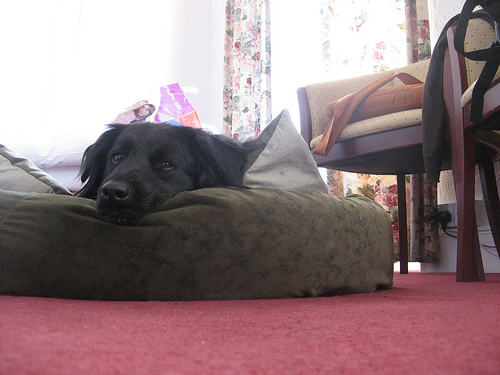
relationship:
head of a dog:
[95, 122, 199, 221] [75, 115, 258, 234]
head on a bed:
[95, 122, 199, 221] [5, 146, 396, 309]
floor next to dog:
[1, 270, 500, 372] [75, 115, 258, 234]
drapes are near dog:
[223, 1, 437, 267] [75, 115, 258, 234]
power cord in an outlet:
[435, 207, 497, 251] [435, 202, 457, 226]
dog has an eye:
[75, 115, 258, 234] [160, 159, 173, 169]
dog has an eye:
[75, 115, 258, 234] [113, 151, 124, 162]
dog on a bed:
[75, 115, 258, 234] [5, 146, 396, 309]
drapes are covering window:
[223, 1, 437, 267] [271, 3, 405, 178]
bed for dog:
[5, 146, 396, 309] [75, 115, 258, 234]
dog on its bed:
[75, 115, 258, 234] [5, 146, 396, 309]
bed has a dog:
[5, 146, 396, 309] [75, 115, 258, 234]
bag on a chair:
[312, 71, 424, 156] [298, 6, 500, 276]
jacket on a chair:
[420, 9, 496, 185] [436, 11, 496, 280]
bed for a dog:
[5, 146, 396, 309] [75, 115, 258, 234]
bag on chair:
[312, 71, 424, 156] [298, 6, 500, 276]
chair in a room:
[298, 6, 500, 276] [6, 3, 499, 374]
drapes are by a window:
[223, 1, 437, 267] [271, 3, 405, 178]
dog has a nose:
[75, 115, 258, 234] [101, 179, 130, 201]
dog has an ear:
[75, 115, 258, 234] [194, 130, 247, 186]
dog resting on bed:
[75, 115, 258, 234] [5, 146, 396, 309]